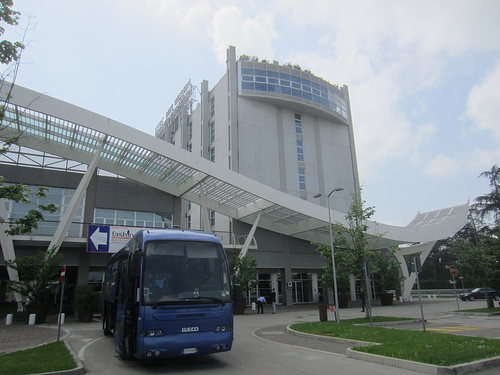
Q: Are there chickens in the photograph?
A: No, there are no chickens.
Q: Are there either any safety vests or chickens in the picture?
A: No, there are no chickens or safety vests.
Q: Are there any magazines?
A: No, there are no magazines.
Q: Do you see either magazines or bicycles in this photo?
A: No, there are no magazines or bicycles.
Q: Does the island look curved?
A: Yes, the island is curved.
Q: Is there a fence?
A: No, there are no fences.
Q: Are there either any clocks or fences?
A: No, there are no fences or clocks.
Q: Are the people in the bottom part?
A: Yes, the people are in the bottom of the image.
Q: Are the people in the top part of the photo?
A: No, the people are in the bottom of the image.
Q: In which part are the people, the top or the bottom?
A: The people are in the bottom of the image.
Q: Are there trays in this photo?
A: No, there are no trays.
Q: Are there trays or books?
A: No, there are no trays or books.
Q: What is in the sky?
A: The clouds are in the sky.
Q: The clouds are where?
A: The clouds are in the sky.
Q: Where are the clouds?
A: The clouds are in the sky.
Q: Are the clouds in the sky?
A: Yes, the clouds are in the sky.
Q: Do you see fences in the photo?
A: No, there are no fences.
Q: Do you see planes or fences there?
A: No, there are no fences or planes.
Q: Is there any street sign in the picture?
A: Yes, there is a street sign.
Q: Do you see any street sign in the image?
A: Yes, there is a street sign.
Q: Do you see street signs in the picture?
A: Yes, there is a street sign.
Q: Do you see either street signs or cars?
A: Yes, there is a street sign.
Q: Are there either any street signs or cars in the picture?
A: Yes, there is a street sign.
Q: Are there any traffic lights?
A: No, there are no traffic lights.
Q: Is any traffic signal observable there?
A: No, there are no traffic lights.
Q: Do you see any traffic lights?
A: No, there are no traffic lights.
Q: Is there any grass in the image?
A: Yes, there is grass.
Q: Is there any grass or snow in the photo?
A: Yes, there is grass.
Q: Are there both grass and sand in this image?
A: No, there is grass but no sand.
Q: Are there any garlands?
A: No, there are no garlands.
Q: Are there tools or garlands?
A: No, there are no garlands or tools.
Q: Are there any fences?
A: No, there are no fences.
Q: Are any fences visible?
A: No, there are no fences.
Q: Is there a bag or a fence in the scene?
A: No, there are no fences or bags.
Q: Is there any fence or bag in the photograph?
A: No, there are no fences or bags.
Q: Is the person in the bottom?
A: Yes, the person is in the bottom of the image.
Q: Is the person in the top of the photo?
A: No, the person is in the bottom of the image.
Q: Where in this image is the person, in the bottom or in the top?
A: The person is in the bottom of the image.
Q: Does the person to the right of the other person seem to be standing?
A: Yes, the person is standing.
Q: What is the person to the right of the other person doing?
A: The person is standing.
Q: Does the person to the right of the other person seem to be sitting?
A: No, the person is standing.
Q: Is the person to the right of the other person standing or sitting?
A: The person is standing.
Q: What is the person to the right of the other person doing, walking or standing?
A: The person is standing.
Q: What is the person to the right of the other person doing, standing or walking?
A: The person is standing.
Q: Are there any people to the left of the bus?
A: No, the person is to the right of the bus.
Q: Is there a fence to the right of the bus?
A: No, there is a person to the right of the bus.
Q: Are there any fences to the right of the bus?
A: No, there is a person to the right of the bus.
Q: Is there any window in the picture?
A: Yes, there are windows.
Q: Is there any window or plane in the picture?
A: Yes, there are windows.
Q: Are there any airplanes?
A: No, there are no airplanes.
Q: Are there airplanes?
A: No, there are no airplanes.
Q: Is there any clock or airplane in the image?
A: No, there are no airplanes or clocks.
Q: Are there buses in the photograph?
A: Yes, there is a bus.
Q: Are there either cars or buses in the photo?
A: Yes, there is a bus.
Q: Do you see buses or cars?
A: Yes, there is a bus.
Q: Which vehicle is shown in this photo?
A: The vehicle is a bus.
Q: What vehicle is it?
A: The vehicle is a bus.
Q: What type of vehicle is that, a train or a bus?
A: This is a bus.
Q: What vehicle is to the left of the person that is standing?
A: The vehicle is a bus.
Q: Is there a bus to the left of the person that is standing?
A: Yes, there is a bus to the left of the person.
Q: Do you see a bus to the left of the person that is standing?
A: Yes, there is a bus to the left of the person.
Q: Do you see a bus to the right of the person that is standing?
A: No, the bus is to the left of the person.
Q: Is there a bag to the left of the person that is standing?
A: No, there is a bus to the left of the person.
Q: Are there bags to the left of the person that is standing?
A: No, there is a bus to the left of the person.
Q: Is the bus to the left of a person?
A: Yes, the bus is to the left of a person.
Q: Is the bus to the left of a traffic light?
A: No, the bus is to the left of a person.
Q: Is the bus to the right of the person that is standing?
A: No, the bus is to the left of the person.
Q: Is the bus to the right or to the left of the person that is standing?
A: The bus is to the left of the person.